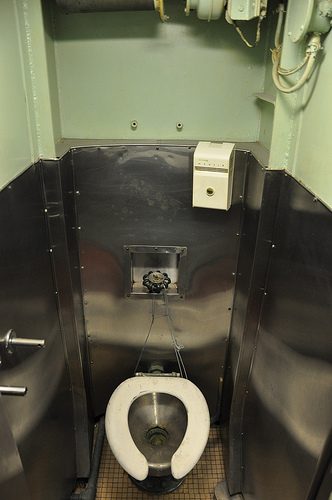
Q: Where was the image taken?
A: It was taken at the bathroom.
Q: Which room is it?
A: It is a bathroom.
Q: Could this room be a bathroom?
A: Yes, it is a bathroom.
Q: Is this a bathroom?
A: Yes, it is a bathroom.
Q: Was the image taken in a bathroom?
A: Yes, it was taken in a bathroom.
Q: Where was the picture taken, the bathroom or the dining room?
A: It was taken at the bathroom.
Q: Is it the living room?
A: No, it is the bathroom.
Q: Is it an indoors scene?
A: Yes, it is indoors.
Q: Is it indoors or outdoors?
A: It is indoors.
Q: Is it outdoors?
A: No, it is indoors.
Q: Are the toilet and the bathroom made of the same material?
A: Yes, both the toilet and the bathroom are made of metal.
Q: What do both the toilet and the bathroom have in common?
A: The material, both the toilet and the bathroom are metallic.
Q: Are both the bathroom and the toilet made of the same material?
A: Yes, both the bathroom and the toilet are made of metal.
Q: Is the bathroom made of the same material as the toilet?
A: Yes, both the bathroom and the toilet are made of metal.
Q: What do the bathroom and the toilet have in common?
A: The material, both the bathroom and the toilet are metallic.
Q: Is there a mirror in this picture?
A: No, there are no mirrors.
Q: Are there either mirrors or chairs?
A: No, there are no mirrors or chairs.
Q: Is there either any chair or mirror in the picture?
A: No, there are no mirrors or chairs.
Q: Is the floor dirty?
A: Yes, the floor is dirty.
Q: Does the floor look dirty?
A: Yes, the floor is dirty.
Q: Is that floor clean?
A: No, the floor is dirty.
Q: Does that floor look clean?
A: No, the floor is dirty.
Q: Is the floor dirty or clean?
A: The floor is dirty.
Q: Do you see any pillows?
A: No, there are no pillows.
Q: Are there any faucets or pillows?
A: No, there are no pillows or faucets.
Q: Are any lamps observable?
A: No, there are no lamps.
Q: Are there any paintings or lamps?
A: No, there are no lamps or paintings.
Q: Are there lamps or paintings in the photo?
A: No, there are no lamps or paintings.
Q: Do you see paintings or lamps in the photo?
A: No, there are no lamps or paintings.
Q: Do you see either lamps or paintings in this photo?
A: No, there are no lamps or paintings.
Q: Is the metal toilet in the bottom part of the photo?
A: Yes, the toilet is in the bottom of the image.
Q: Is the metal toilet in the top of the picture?
A: No, the toilet is in the bottom of the image.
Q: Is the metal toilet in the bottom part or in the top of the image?
A: The toilet is in the bottom of the image.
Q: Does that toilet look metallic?
A: Yes, the toilet is metallic.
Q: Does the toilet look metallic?
A: Yes, the toilet is metallic.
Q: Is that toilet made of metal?
A: Yes, the toilet is made of metal.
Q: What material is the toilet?
A: The toilet is made of metal.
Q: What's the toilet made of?
A: The toilet is made of metal.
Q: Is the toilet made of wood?
A: No, the toilet is made of metal.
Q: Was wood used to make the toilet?
A: No, the toilet is made of metal.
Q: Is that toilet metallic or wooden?
A: The toilet is metallic.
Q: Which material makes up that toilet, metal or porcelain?
A: The toilet is made of metal.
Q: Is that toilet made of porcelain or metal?
A: The toilet is made of metal.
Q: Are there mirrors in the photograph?
A: No, there are no mirrors.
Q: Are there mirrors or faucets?
A: No, there are no mirrors or faucets.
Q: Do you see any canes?
A: No, there are no canes.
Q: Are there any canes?
A: No, there are no canes.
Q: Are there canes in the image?
A: No, there are no canes.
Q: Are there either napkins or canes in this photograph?
A: No, there are no canes or napkins.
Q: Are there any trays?
A: No, there are no trays.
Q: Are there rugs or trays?
A: No, there are no trays or rugs.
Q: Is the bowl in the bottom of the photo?
A: Yes, the bowl is in the bottom of the image.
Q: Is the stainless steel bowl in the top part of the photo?
A: No, the bowl is in the bottom of the image.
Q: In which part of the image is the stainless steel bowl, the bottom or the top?
A: The bowl is in the bottom of the image.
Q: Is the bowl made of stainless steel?
A: Yes, the bowl is made of stainless steel.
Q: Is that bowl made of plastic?
A: No, the bowl is made of stainless steel.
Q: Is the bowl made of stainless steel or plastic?
A: The bowl is made of stainless steel.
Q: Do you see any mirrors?
A: No, there are no mirrors.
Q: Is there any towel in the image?
A: No, there are no towels.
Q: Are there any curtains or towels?
A: No, there are no towels or curtains.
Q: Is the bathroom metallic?
A: Yes, the bathroom is metallic.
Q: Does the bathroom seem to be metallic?
A: Yes, the bathroom is metallic.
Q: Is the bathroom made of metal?
A: Yes, the bathroom is made of metal.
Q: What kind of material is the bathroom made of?
A: The bathroom is made of metal.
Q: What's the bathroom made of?
A: The bathroom is made of metal.